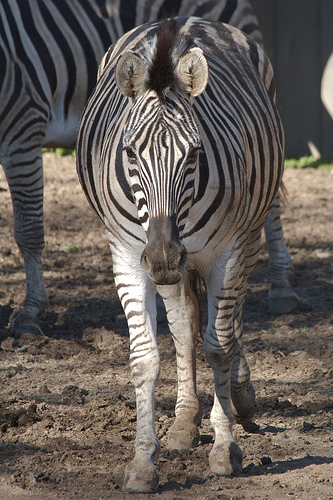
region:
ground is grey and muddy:
[10, 352, 324, 498]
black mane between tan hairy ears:
[109, 31, 225, 97]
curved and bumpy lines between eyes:
[117, 131, 203, 164]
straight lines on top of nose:
[140, 176, 169, 212]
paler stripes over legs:
[100, 256, 202, 406]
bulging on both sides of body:
[66, 105, 299, 208]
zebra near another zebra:
[4, 10, 197, 296]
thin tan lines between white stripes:
[16, 18, 87, 73]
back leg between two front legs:
[107, 231, 239, 446]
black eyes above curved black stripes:
[113, 142, 200, 162]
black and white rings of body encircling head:
[101, 110, 227, 253]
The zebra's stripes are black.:
[68, 12, 308, 492]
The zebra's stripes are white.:
[70, 12, 302, 495]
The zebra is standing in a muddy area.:
[0, 157, 332, 498]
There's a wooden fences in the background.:
[245, 0, 330, 164]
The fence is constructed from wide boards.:
[252, 0, 332, 161]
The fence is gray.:
[245, 1, 332, 156]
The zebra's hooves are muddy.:
[79, 391, 274, 492]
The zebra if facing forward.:
[98, 73, 230, 299]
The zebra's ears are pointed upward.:
[108, 46, 218, 108]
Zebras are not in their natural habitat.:
[2, 0, 330, 498]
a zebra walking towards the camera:
[69, 11, 296, 489]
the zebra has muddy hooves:
[123, 390, 253, 489]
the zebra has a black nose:
[137, 214, 184, 280]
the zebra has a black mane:
[143, 16, 176, 93]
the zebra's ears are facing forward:
[113, 47, 207, 99]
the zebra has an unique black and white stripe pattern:
[74, 13, 292, 457]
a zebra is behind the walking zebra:
[3, 0, 279, 339]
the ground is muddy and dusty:
[2, 150, 325, 495]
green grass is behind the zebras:
[37, 131, 327, 170]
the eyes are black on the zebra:
[118, 141, 199, 167]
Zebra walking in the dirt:
[104, 384, 263, 484]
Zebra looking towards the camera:
[94, 163, 227, 329]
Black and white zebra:
[73, 43, 276, 289]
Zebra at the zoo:
[63, 70, 304, 288]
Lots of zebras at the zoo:
[32, 12, 298, 246]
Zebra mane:
[131, 51, 199, 101]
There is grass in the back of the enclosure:
[292, 134, 331, 184]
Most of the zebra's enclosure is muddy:
[85, 388, 232, 464]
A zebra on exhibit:
[33, 49, 295, 223]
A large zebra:
[28, 29, 308, 276]